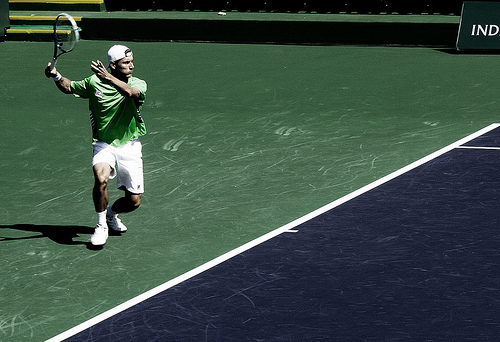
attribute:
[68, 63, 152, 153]
shirt — green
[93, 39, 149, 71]
cap — white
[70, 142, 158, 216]
shorts — white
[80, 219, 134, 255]
shoes — white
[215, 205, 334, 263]
lines — white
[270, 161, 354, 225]
floor — green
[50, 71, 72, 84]
wristband — white